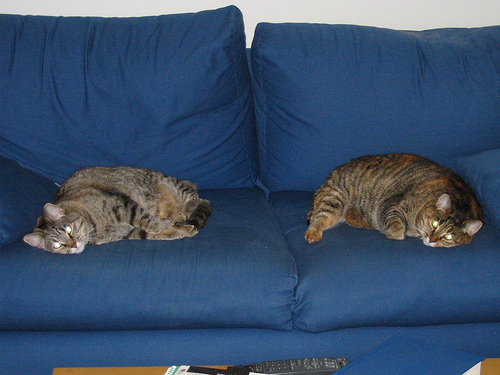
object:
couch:
[137, 28, 275, 168]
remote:
[225, 352, 347, 374]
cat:
[23, 164, 213, 253]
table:
[101, 365, 134, 373]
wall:
[327, 2, 397, 17]